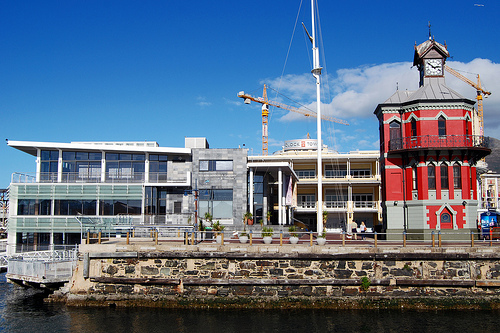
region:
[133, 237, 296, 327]
a brick retaining wall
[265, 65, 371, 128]
a cloud in the sky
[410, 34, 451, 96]
a clock tower of a building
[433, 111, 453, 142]
a window of a building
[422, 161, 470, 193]
the windows of a building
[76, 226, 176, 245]
a fence on a platform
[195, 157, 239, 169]
a window of a building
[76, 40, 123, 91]
the clear blue sky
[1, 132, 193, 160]
the roof a building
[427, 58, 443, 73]
the clock face of a clock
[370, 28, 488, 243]
a red and grey building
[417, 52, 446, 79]
a white and black clock face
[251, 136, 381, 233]
a tan building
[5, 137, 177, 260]
a white and green building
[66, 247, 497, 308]
a brown brick wall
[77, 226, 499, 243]
brown protective fencing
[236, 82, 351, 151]
a tall yellow crane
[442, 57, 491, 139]
a tall yellow crane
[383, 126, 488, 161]
a rounded observation deck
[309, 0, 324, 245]
a tall white flag pole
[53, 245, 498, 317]
stone wall by water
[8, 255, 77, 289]
boat sitting in water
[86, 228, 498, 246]
wood and metal fence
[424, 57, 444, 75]
white and black clock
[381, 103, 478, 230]
red painted building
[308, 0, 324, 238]
white metal electrical pole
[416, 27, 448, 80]
grey metal clock tower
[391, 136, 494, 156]
black metal patio deck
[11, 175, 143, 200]
glass and white metal railing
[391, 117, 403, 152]
glass door by patio deck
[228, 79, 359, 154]
a yellow and whie crane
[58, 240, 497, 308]
a rock wall at the water's edge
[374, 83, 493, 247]
a red building by the water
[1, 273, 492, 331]
dark water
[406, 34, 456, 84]
a cupola with a clock on top of a red building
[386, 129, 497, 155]
a balcony on a red building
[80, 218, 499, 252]
a railing on the edge of a wharf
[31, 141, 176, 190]
glass walls lining the side of a building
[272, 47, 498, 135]
a puffy white cloud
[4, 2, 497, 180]
a beautiful blue sky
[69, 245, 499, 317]
stone fence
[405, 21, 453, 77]
clocktower clock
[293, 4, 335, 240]
white mast or flag pole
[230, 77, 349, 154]
construction crane in the background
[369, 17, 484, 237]
red clocktower or lighthouse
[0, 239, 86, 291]
balcony overlooking water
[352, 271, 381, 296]
moss growing on side of stone wall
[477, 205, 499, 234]
advertising on the side of building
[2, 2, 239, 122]
cerulean blue sky with only a few wisps of clouds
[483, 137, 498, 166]
mountainous terrain in the background